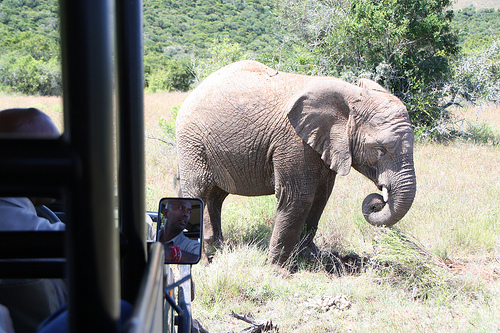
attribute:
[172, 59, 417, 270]
elephant — large, grey, standing, eating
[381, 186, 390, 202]
tusk — short, white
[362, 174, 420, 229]
trunk — curled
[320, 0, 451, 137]
tree — green, large, bushy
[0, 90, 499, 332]
grass — green, tall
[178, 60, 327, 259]
skin — wrinkled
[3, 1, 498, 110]
foliage — green